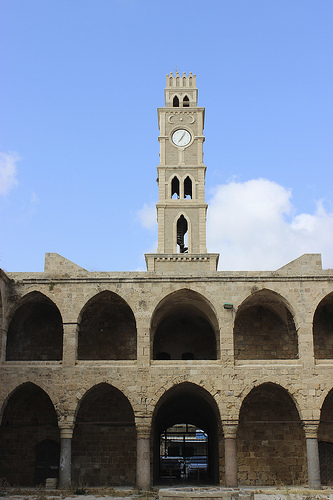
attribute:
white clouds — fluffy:
[214, 181, 292, 251]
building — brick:
[102, 35, 260, 375]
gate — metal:
[157, 411, 216, 479]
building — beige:
[11, 268, 308, 497]